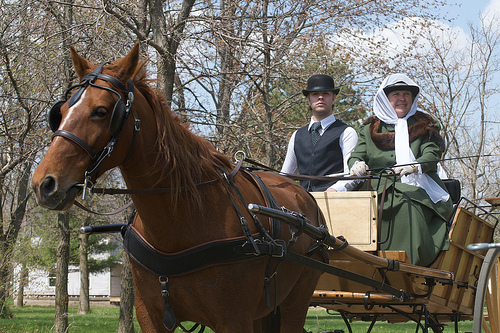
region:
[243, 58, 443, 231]
man and woman riding in carriage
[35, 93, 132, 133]
horse has blinders on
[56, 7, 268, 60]
trees behind the horse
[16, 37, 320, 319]
brown horse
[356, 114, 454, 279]
woman is wearing a green dress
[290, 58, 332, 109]
man is wearing a black hat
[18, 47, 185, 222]
head of a horse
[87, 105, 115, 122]
eye of a horse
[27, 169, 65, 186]
nose of a horse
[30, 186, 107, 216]
mouth of a horse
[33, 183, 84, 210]
mouth of a horse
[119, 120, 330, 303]
body of a horse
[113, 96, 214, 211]
neck of a horse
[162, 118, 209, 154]
hair of a horse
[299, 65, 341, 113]
head of a person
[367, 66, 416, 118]
head of a person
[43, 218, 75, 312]
Slinder brown tree trunks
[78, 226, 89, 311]
Slinder brown tree trunks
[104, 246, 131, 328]
Slinder brown tree trunks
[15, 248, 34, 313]
Slinder brown tree trunks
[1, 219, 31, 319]
Slinder brown tree trunks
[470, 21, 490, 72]
Small brown branches on a tree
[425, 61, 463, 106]
Small brown branches on a tree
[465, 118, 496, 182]
Small brown branches on a tree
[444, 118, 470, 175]
Small brown branches on a tree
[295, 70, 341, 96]
Black hat on head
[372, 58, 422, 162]
White scarf on womans head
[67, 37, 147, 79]
Two brown horse ears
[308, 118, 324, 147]
tie that is tucked in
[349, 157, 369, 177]
White glove on womans hand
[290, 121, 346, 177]
Black vest and tie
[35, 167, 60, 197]
The horses right nostril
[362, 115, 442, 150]
Brown fur around womans neck and chest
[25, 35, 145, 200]
The brown horses face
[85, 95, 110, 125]
The right eye on the horse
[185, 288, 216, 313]
Small patch of brown fur on a horse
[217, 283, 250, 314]
Small patch of brown fur on a horse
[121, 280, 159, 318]
Small patch of brown fur on a horse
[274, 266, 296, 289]
Small patch of brown fur on a horse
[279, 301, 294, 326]
Small patch of brown fur on a horse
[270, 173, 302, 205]
Small patch of brown fur on a horse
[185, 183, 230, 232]
Small patch of brown fur on a horse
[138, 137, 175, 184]
Small patch of brown fur on a horse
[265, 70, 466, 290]
a man and woman settng in a cart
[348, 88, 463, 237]
A woman in a green jacket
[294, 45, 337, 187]
A man in a black hat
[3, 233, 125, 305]
And White House in the background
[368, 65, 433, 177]
A woman with a white scarf on her head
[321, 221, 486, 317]
A brown wagon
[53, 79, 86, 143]
A white marker on the horses head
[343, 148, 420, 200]
Woman with white gloves on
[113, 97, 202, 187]
Horses brown Maine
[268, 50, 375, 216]
man with a black hat on driving the horse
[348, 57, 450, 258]
lady with a green coat and a brown scarf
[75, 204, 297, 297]
bridle on the brown horse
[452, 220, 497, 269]
metal screw in the side of the carriage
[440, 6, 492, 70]
blue sky in the distance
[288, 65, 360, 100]
black hat on the mans head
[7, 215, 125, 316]
white house off in the distance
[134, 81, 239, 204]
brown horse mane on the horses neck